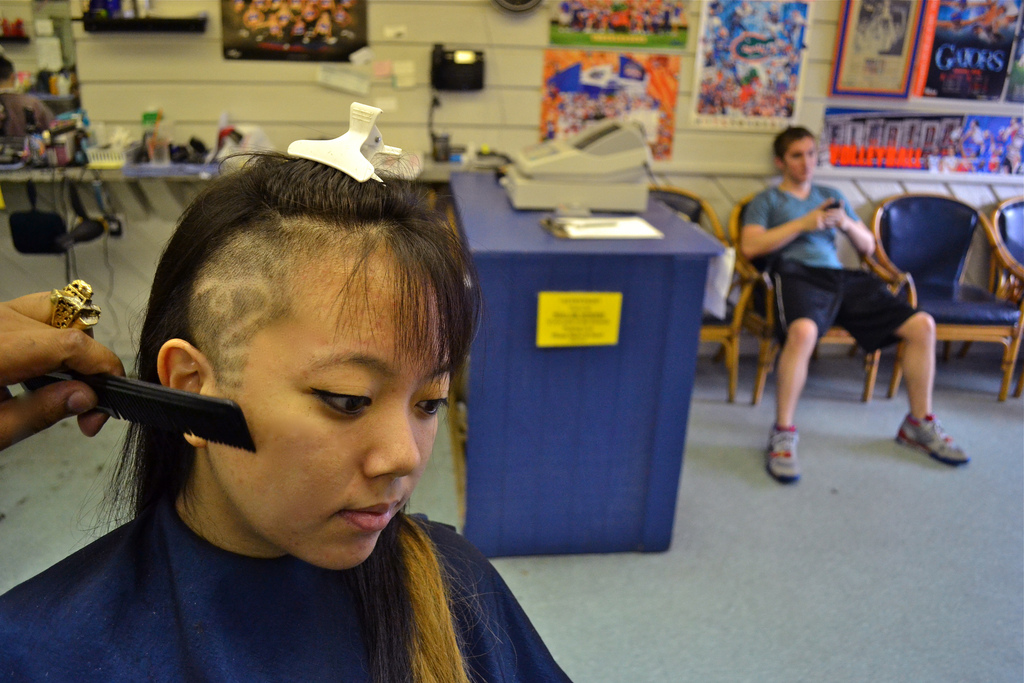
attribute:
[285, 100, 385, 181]
hair clip — white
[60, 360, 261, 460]
comb — black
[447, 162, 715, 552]
desk — blue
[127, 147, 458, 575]
head — half-shaved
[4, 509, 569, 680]
cloth — blue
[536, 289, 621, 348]
sign — yellow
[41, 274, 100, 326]
ring — gold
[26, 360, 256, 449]
comb — black